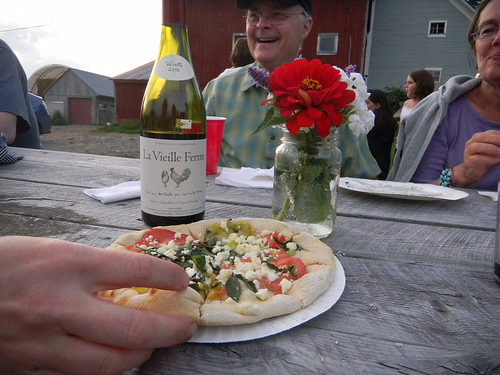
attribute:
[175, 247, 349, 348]
dish — white, paper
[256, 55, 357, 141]
flower — red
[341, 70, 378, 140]
flower — white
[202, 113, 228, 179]
glass — plastic, red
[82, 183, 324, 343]
pizza — personal size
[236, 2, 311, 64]
man — SMILING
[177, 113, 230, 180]
cup — red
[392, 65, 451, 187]
girl — behind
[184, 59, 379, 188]
shirt — yellow and blue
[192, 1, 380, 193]
man — older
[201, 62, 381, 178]
shirt — plaid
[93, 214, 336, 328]
pizza — small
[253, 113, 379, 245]
jar — mason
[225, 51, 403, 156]
zinnia — red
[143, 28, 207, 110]
bottle — wine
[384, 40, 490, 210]
girl — young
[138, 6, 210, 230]
bottle — half empty, green, grass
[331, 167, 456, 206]
plate — empty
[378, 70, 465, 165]
sweater — gray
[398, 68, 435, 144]
girl — young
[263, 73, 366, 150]
daisy — red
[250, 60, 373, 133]
arrangement — flower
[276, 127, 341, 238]
jar — glass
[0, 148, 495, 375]
table — made of wood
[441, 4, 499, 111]
woman — old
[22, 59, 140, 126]
structure — wood